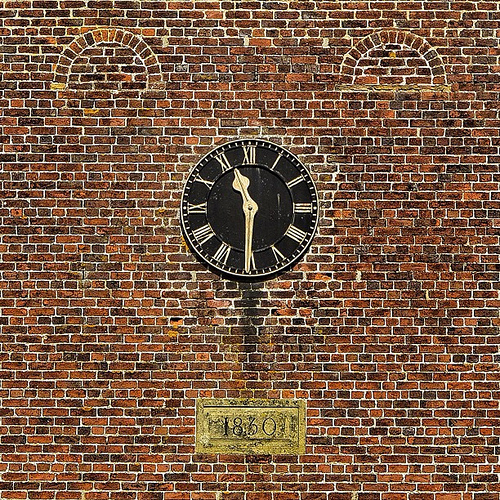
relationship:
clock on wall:
[179, 139, 320, 282] [5, 18, 496, 498]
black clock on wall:
[179, 137, 319, 276] [5, 18, 496, 498]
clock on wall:
[179, 139, 320, 282] [50, 55, 417, 466]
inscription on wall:
[217, 412, 277, 439] [5, 18, 496, 498]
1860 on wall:
[224, 417, 278, 436] [115, 329, 472, 490]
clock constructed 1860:
[179, 139, 320, 282] [193, 391, 315, 462]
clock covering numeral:
[179, 140, 317, 280] [247, 248, 263, 265]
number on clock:
[285, 191, 324, 221] [172, 137, 315, 273]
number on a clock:
[282, 170, 311, 197] [179, 140, 317, 280]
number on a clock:
[238, 144, 265, 170] [179, 140, 317, 280]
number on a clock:
[209, 148, 231, 170] [172, 137, 315, 273]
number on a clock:
[186, 223, 216, 252] [179, 139, 320, 282]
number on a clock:
[209, 237, 235, 268] [172, 143, 322, 283]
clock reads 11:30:
[179, 139, 320, 282] [197, 144, 269, 276]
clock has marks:
[179, 139, 320, 282] [232, 148, 269, 180]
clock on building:
[179, 140, 317, 280] [2, 0, 496, 497]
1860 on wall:
[224, 417, 278, 436] [5, 18, 496, 498]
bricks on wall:
[392, 174, 441, 186] [5, 18, 496, 498]